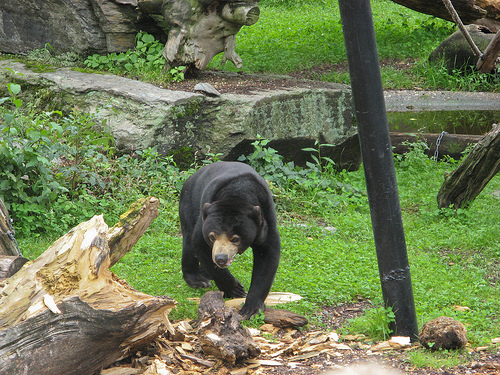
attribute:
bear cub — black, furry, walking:
[180, 158, 290, 315]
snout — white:
[210, 239, 235, 267]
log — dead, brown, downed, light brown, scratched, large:
[6, 203, 180, 375]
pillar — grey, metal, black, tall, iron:
[337, 3, 418, 347]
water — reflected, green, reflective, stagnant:
[381, 102, 499, 138]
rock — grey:
[24, 68, 352, 167]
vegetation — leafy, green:
[8, 77, 164, 238]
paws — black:
[180, 272, 259, 316]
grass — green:
[23, 177, 500, 375]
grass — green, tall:
[205, 0, 490, 84]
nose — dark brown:
[215, 254, 228, 265]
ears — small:
[196, 199, 264, 224]